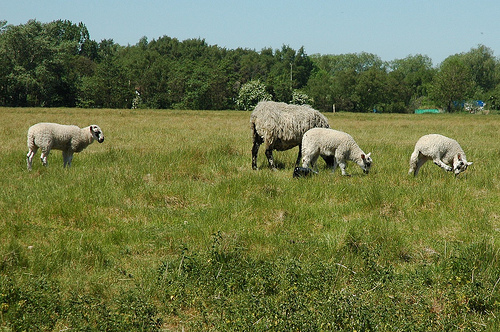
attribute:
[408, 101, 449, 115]
fence — green 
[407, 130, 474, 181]
sheep — White 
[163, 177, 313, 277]
grass — green 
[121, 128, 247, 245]
field — green 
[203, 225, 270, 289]
grass — green 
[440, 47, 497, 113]
trees — green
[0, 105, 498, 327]
green grass — small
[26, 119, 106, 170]
sheep — White 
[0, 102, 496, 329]
grass — green 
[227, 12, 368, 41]
skies — blue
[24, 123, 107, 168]
sheep — wooly, white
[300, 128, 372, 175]
sheep — white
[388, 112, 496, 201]
lamb — white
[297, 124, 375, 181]
sheep — white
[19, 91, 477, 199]
lambs — white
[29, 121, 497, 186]
sheep — white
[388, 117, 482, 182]
lamb — wooly, white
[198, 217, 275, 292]
grass — green 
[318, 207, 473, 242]
grass — green 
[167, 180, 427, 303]
grass — green 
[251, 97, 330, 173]
sheep — white, largest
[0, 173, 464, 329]
field — grassy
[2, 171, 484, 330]
weeds — green